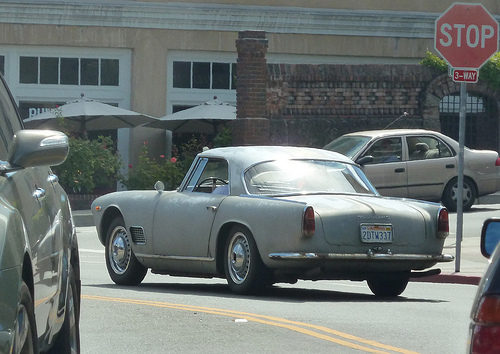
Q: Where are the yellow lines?
A: Middle of the road.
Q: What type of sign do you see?
A: I can see stop sign.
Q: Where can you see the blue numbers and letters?
A: They are on the license plate.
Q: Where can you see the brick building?
A: Next to the tan car.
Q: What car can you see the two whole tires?
A: On the small grey sports car.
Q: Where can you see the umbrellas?
A: Next to the building.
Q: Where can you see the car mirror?
A: On the left behind the grey small car.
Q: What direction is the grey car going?
A: Direction of the umbrellas.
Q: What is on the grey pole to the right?
A: A stop sign is there.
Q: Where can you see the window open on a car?
A: On the left driver side of grey car.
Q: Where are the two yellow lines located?
A: They are on the ground.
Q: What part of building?
A: Side wall.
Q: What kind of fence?
A: Brick.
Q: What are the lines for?
A: Separate sides of road.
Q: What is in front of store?
A: Umbrellas.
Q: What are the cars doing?
A: Driving.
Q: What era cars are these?
A: Older.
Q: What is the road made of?
A: Asphalt.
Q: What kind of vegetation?
A: Bushes.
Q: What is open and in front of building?
A: Umbrella.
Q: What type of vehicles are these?
A: Cars.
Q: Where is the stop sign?
A: Far right.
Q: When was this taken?
A: Day time.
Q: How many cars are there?
A: Four.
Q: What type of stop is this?
A: Three-way.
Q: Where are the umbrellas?
A: Upper left quadrant.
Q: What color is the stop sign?
A: Red.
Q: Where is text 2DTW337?
A: License plate.